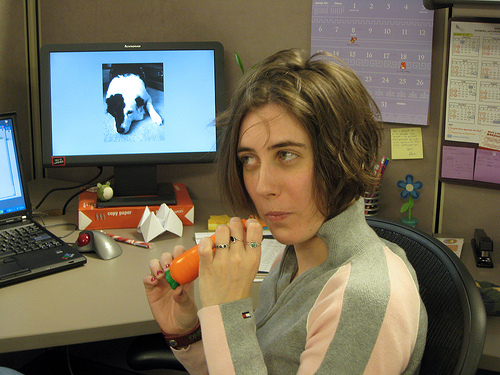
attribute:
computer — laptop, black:
[0, 112, 86, 289]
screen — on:
[40, 40, 222, 164]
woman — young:
[140, 45, 430, 373]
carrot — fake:
[160, 218, 266, 289]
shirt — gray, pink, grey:
[170, 200, 429, 374]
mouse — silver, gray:
[73, 227, 126, 263]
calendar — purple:
[306, 1, 435, 125]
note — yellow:
[390, 125, 427, 164]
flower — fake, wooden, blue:
[394, 172, 426, 225]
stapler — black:
[471, 225, 497, 270]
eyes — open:
[238, 150, 300, 166]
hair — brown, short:
[210, 48, 385, 219]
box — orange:
[77, 182, 195, 230]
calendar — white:
[442, 19, 499, 145]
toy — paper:
[139, 203, 187, 243]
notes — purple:
[435, 145, 499, 186]